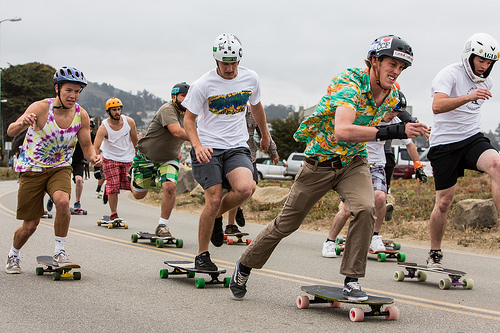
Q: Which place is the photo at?
A: It is at the road.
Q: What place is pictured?
A: It is a road.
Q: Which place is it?
A: It is a road.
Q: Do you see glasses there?
A: No, there are no glasses.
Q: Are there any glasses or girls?
A: No, there are no glasses or girls.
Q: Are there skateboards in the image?
A: Yes, there is a skateboard.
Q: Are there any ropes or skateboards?
A: Yes, there is a skateboard.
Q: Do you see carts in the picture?
A: No, there are no carts.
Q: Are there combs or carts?
A: No, there are no carts or combs.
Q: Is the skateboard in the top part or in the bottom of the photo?
A: The skateboard is in the bottom of the image.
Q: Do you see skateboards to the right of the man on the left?
A: Yes, there is a skateboard to the right of the man.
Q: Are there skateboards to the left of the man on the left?
A: No, the skateboard is to the right of the man.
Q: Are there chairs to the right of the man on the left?
A: No, there is a skateboard to the right of the man.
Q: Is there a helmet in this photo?
A: Yes, there is a helmet.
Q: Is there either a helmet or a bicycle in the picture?
A: Yes, there is a helmet.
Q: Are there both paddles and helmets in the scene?
A: No, there is a helmet but no paddles.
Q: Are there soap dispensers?
A: No, there are no soap dispensers.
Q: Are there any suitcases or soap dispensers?
A: No, there are no soap dispensers or suitcases.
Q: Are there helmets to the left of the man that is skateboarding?
A: Yes, there is a helmet to the left of the man.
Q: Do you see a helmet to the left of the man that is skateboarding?
A: Yes, there is a helmet to the left of the man.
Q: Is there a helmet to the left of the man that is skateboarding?
A: Yes, there is a helmet to the left of the man.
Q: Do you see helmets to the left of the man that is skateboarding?
A: Yes, there is a helmet to the left of the man.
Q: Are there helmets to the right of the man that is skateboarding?
A: No, the helmet is to the left of the man.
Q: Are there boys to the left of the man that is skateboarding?
A: No, there is a helmet to the left of the man.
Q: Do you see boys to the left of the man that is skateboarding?
A: No, there is a helmet to the left of the man.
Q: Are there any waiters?
A: No, there are no waiters.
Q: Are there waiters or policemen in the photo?
A: No, there are no waiters or policemen.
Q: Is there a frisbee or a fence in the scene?
A: No, there are no frisbees or fences.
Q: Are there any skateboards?
A: Yes, there is a skateboard.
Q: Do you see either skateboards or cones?
A: Yes, there is a skateboard.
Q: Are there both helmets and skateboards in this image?
A: Yes, there are both a skateboard and a helmet.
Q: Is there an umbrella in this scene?
A: No, there are no umbrellas.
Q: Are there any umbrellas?
A: No, there are no umbrellas.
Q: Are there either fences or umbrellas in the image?
A: No, there are no umbrellas or fences.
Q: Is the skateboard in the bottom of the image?
A: Yes, the skateboard is in the bottom of the image.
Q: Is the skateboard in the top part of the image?
A: No, the skateboard is in the bottom of the image.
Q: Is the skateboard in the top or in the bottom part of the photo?
A: The skateboard is in the bottom of the image.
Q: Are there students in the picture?
A: No, there are no students.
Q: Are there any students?
A: No, there are no students.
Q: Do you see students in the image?
A: No, there are no students.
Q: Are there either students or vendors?
A: No, there are no students or vendors.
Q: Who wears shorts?
A: The man wears shorts.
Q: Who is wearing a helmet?
A: The man is wearing a helmet.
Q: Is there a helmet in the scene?
A: Yes, there is a helmet.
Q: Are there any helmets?
A: Yes, there is a helmet.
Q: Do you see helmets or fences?
A: Yes, there is a helmet.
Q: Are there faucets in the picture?
A: No, there are no faucets.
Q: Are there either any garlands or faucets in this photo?
A: No, there are no faucets or garlands.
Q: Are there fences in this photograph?
A: No, there are no fences.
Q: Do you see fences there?
A: No, there are no fences.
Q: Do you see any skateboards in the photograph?
A: Yes, there is a skateboard.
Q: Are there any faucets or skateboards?
A: Yes, there is a skateboard.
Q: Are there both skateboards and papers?
A: No, there is a skateboard but no papers.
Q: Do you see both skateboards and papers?
A: No, there is a skateboard but no papers.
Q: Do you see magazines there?
A: No, there are no magazines.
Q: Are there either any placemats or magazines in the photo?
A: No, there are no magazines or placemats.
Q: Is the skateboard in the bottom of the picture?
A: Yes, the skateboard is in the bottom of the image.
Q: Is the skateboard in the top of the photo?
A: No, the skateboard is in the bottom of the image.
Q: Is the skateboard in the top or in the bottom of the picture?
A: The skateboard is in the bottom of the image.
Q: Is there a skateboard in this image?
A: Yes, there are skateboards.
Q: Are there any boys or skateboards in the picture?
A: Yes, there are skateboards.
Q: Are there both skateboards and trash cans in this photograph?
A: No, there are skateboards but no trash cans.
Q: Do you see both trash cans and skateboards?
A: No, there are skateboards but no trash cans.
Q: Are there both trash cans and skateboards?
A: No, there are skateboards but no trash cans.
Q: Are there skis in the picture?
A: No, there are no skis.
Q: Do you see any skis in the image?
A: No, there are no skis.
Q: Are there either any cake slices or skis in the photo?
A: No, there are no skis or cake slices.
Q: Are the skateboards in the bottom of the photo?
A: Yes, the skateboards are in the bottom of the image.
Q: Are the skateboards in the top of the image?
A: No, the skateboards are in the bottom of the image.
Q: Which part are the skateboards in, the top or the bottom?
A: The skateboards are in the bottom of the image.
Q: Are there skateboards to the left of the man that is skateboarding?
A: Yes, there are skateboards to the left of the man.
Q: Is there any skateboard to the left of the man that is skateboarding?
A: Yes, there are skateboards to the left of the man.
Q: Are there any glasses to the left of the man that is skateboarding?
A: No, there are skateboards to the left of the man.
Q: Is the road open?
A: Yes, the road is open.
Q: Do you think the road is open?
A: Yes, the road is open.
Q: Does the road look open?
A: Yes, the road is open.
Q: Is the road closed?
A: No, the road is open.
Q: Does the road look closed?
A: No, the road is open.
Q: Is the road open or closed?
A: The road is open.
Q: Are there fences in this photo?
A: No, there are no fences.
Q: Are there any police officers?
A: No, there are no police officers.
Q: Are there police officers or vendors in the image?
A: No, there are no police officers or vendors.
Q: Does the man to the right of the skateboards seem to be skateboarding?
A: Yes, the man is skateboarding.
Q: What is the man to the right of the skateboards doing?
A: The man is skateboarding.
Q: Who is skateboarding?
A: The man is skateboarding.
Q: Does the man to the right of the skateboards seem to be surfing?
A: No, the man is skateboarding.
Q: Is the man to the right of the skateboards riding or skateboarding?
A: The man is skateboarding.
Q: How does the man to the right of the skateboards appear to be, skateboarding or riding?
A: The man is skateboarding.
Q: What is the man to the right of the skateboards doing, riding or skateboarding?
A: The man is skateboarding.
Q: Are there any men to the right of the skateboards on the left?
A: Yes, there is a man to the right of the skateboards.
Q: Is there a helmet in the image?
A: Yes, there is a helmet.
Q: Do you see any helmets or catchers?
A: Yes, there is a helmet.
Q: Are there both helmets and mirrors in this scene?
A: No, there is a helmet but no mirrors.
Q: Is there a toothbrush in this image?
A: No, there are no toothbrushes.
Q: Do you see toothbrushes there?
A: No, there are no toothbrushes.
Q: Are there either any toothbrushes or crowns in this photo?
A: No, there are no toothbrushes or crowns.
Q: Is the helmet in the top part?
A: Yes, the helmet is in the top of the image.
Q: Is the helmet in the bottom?
A: No, the helmet is in the top of the image.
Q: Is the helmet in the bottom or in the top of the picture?
A: The helmet is in the top of the image.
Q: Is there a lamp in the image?
A: No, there are no lamps.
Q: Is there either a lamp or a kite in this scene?
A: No, there are no lamps or kites.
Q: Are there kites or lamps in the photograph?
A: No, there are no lamps or kites.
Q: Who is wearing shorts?
A: The man is wearing shorts.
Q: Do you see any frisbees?
A: No, there are no frisbees.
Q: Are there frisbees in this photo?
A: No, there are no frisbees.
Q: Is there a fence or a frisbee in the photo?
A: No, there are no frisbees or fences.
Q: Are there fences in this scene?
A: No, there are no fences.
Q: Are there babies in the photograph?
A: No, there are no babies.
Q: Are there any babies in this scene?
A: No, there are no babies.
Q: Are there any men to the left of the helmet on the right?
A: Yes, there is a man to the left of the helmet.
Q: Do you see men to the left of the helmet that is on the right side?
A: Yes, there is a man to the left of the helmet.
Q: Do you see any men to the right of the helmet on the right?
A: No, the man is to the left of the helmet.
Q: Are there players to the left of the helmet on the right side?
A: No, there is a man to the left of the helmet.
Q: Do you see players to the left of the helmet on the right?
A: No, there is a man to the left of the helmet.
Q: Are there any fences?
A: No, there are no fences.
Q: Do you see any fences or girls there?
A: No, there are no fences or girls.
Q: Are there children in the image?
A: No, there are no children.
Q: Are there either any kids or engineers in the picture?
A: No, there are no kids or engineers.